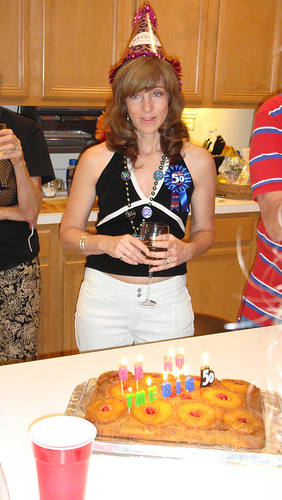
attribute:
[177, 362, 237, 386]
candle — burning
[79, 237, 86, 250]
bracelet — golden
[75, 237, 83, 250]
bracelet — golden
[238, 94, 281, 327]
top — red,blue and white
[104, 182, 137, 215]
shirt — black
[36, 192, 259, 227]
countertop — white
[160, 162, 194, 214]
ribbon — blue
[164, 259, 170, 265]
ring — gold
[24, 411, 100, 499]
cup — red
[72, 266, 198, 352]
pants — white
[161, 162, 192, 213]
ribbon — birthday girl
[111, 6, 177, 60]
hat — pointed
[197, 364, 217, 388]
candle — black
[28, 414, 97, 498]
cup — red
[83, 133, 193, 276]
top — black, white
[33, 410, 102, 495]
cup — red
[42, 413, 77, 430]
inside — white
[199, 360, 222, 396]
sign — brown and white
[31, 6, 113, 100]
cabinets — brown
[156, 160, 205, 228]
ribbon — blue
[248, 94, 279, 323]
shirt — red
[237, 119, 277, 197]
stripes — blue, white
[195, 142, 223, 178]
holder — well used